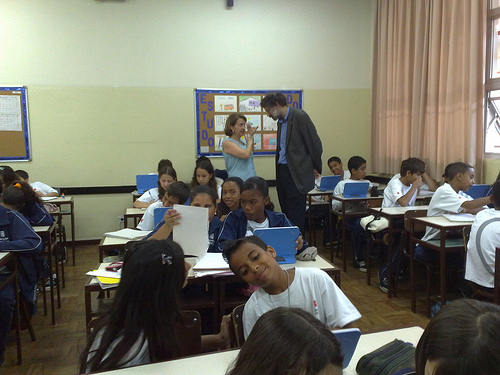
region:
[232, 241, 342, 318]
student at a desk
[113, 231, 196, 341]
student at a desk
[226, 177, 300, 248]
student at a desk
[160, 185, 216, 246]
student at a desk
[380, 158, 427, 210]
student at a desk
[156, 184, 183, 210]
student at a desk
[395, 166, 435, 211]
student at a desk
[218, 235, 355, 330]
A boy is smiling.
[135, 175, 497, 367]
Children have blue laptops.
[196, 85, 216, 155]
ESTUDOon a brownsurface.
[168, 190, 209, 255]
A girl has a paper in her face.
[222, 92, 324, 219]
Two adults are talking.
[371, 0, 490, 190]
A blind is pink.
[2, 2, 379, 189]
A wall is white.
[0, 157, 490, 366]
The children have dark hair.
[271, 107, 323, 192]
A man is wearing a gray jacket.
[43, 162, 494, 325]
Children are wearing white shirts.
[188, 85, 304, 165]
Bulletin board on the wall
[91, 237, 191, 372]
Girl with long black hair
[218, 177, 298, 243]
Girl wearing a blue jacket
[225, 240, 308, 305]
Boy wearing a silver necklace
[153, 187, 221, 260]
Girl looking at a paper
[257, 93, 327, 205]
Man wearing a gray jacket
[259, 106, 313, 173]
Man wearing a blue shirt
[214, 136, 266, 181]
Woman wearing a light blue blouse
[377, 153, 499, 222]
Students sitting at their desks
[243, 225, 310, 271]
Blue laptop computer on a desk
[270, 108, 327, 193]
a grey suit jacket on aman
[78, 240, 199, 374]
long blond hair on a girl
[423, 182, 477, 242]
a white shirt on a girl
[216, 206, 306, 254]
a blue jacket on a girl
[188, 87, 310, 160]
a bulletin board on a wall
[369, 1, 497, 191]
curtains in a window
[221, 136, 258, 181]
a light blue shirt on a wan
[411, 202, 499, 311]
a desk in front of a girl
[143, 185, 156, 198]
a pencil in a girl's hand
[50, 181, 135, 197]
a chair rail on a wall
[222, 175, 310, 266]
girl in front a laptop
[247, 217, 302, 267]
laptop is color blue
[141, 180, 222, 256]
girl holding a paper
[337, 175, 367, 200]
a blue laptop on table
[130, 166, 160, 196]
a blue laptop on table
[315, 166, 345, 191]
a blue laptop on table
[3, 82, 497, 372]
kids in a classroom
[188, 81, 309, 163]
a board behind two people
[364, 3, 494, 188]
the curtain color brown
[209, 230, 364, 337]
boy wearing white tee shirt